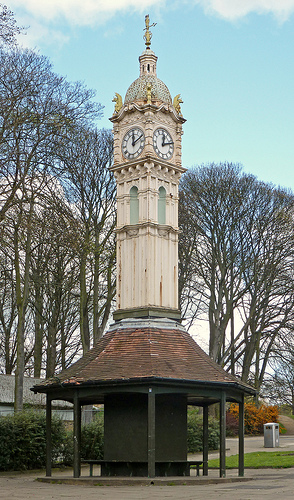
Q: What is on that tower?
A: A clock.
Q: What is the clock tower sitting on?
A: A gazebo.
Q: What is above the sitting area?
A: A roof.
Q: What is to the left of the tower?
A: Leafless trees.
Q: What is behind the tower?
A: Tall trees.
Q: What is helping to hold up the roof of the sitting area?
A: Poles.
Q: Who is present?
A: No one.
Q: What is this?
A: Clock.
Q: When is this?
A: Daytime.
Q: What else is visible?
A: Tower.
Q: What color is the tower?
A: Cream.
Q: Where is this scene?
A: At a square.